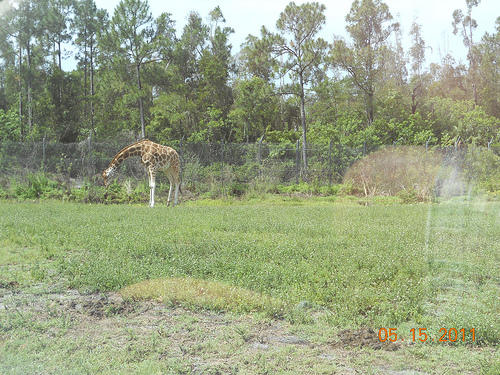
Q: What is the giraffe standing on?
A: Grass.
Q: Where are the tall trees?
A: Behind the giraffe.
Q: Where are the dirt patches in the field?
A: In front of the grass.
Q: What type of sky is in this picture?
A: Blue.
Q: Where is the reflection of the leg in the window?
A: The right.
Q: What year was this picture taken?
A: 2011.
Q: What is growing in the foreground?
A: Grass.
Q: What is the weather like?
A: Sunny.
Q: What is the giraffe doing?
A: Eating.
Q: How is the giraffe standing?
A: Bent over.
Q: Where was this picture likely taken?
A: A zoo.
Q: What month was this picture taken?
A: May.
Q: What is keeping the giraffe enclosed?
A: Fence and glass.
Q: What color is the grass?
A: Green.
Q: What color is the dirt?
A: Brown.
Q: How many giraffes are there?
A: One.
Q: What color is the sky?
A: Blue.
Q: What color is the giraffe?
A: Brown and white.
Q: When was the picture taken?
A: Daytime.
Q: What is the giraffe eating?
A: Plants.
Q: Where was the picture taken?
A: At a zoo.